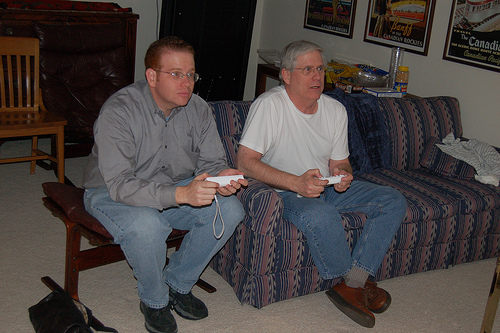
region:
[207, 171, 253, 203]
younger man holds white controller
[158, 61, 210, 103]
younger man wears glasses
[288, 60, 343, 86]
older man wears glasses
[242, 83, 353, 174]
man wears white shirt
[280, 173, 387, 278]
older man wears dark blue jeans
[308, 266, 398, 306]
man wears brown shoes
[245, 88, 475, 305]
man sits on sofa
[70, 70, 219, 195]
man wears grey shirt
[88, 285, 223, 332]
man wears blue shoes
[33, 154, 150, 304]
man sits on brown seat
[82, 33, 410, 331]
Two men playing a video game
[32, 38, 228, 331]
A man sitting on an ottoman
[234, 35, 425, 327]
A man sitting on a couch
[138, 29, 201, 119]
A man with glasses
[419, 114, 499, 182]
A shirt sitting on a couch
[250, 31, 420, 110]
Food sitting on a table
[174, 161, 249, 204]
A video game remote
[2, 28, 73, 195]
A wooden chair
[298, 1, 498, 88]
Framed posters on a wall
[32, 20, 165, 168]
A brown leather recliner.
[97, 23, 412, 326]
two men playing video games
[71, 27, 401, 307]
two men playing wii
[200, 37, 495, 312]
a man sitting on a sofa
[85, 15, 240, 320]
a man sitting on an ottoman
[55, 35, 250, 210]
a man wearing a shirt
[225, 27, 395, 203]
a man wearing a t shirt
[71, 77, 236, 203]
the shirt is gray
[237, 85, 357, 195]
the t shirt is white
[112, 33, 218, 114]
the man has glasses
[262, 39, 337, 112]
the man has glasses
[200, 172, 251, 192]
white wii controller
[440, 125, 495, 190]
white shirt laying on sofa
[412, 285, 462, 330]
white carpet on floor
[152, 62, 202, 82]
pair of silver eyeglasses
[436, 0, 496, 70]
movie poster hanging on wall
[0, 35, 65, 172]
brown wooden chair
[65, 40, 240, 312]
man in grey button up shirt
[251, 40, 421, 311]
man in white tee shirt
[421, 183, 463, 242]
design on sofa cover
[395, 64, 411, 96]
small plastic container of peanuts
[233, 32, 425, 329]
a man sitting on the couch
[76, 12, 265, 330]
a man sitting on a chair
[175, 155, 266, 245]
two hands holding a wii controller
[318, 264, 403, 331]
a pair of men's dress shoes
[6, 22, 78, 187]
a wooden chair in the background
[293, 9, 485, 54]
pictures hanging on the wall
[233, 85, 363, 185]
a white tee shirt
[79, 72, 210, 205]
a grey oxford shirt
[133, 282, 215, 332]
a pair of black tennis shoes